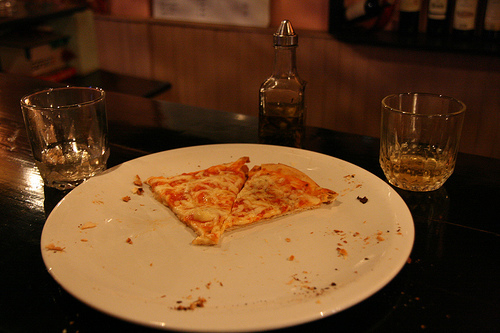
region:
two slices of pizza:
[28, 34, 375, 326]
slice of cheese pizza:
[201, 161, 341, 239]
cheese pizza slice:
[128, 135, 237, 269]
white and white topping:
[168, 169, 230, 233]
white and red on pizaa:
[217, 165, 298, 245]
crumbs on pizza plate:
[89, 165, 166, 290]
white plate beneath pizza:
[298, 195, 422, 304]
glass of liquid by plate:
[396, 79, 464, 162]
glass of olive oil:
[217, 22, 310, 148]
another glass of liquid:
[31, 85, 172, 207]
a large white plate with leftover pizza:
[66, 138, 401, 308]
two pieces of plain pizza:
[142, 155, 337, 246]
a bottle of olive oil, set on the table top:
[246, 15, 308, 157]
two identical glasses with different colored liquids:
[15, 86, 466, 188]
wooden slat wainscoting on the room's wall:
[120, 15, 257, 111]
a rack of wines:
[325, 0, 495, 50]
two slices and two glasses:
[15, 76, 470, 242]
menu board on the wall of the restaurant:
[136, 0, 276, 35]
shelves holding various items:
[0, 0, 105, 85]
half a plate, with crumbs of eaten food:
[33, 237, 423, 328]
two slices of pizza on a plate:
[131, 125, 349, 255]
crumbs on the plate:
[305, 223, 390, 263]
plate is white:
[66, 198, 181, 291]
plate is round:
[48, 150, 446, 311]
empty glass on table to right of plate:
[372, 80, 471, 202]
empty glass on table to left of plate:
[22, 63, 112, 191]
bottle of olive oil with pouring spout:
[251, 4, 311, 159]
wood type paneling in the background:
[103, 13, 246, 113]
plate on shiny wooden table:
[10, 152, 44, 224]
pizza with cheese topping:
[135, 155, 328, 255]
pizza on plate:
[136, 153, 323, 230]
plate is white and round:
[86, 122, 421, 332]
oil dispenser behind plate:
[252, 13, 317, 135]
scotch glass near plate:
[357, 55, 458, 207]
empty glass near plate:
[35, 67, 107, 194]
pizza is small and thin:
[127, 150, 336, 242]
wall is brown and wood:
[113, 30, 391, 102]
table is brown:
[7, 160, 454, 330]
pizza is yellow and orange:
[140, 155, 345, 260]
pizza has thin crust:
[149, 130, 345, 272]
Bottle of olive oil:
[258, 12, 308, 148]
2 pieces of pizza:
[145, 158, 337, 247]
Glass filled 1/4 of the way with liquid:
[372, 80, 473, 196]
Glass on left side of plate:
[10, 80, 116, 187]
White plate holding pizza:
[38, 132, 413, 329]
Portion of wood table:
[411, 194, 492, 329]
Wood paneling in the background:
[107, 16, 241, 76]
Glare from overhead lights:
[0, 143, 46, 208]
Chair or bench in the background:
[80, 61, 183, 99]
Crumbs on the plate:
[158, 275, 225, 315]